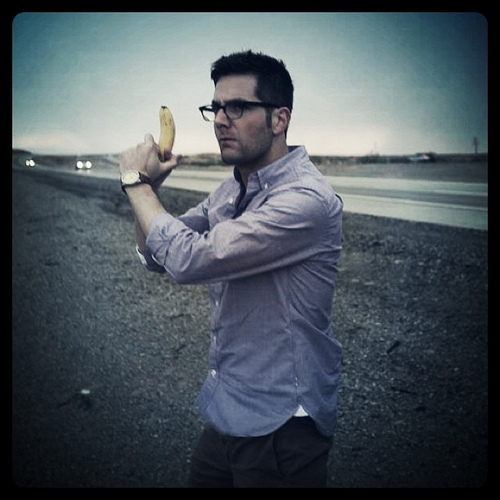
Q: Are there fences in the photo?
A: No, there are no fences.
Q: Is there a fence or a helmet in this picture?
A: No, there are no fences or helmets.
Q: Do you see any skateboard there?
A: No, there are no skateboards.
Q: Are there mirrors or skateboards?
A: No, there are no skateboards or mirrors.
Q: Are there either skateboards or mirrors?
A: No, there are no skateboards or mirrors.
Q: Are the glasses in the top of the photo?
A: Yes, the glasses are in the top of the image.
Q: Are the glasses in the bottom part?
A: No, the glasses are in the top of the image.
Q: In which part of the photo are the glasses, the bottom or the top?
A: The glasses are in the top of the image.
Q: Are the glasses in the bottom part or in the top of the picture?
A: The glasses are in the top of the image.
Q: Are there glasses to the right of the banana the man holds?
A: Yes, there are glasses to the right of the banana.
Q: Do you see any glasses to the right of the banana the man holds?
A: Yes, there are glasses to the right of the banana.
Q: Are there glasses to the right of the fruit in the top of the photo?
A: Yes, there are glasses to the right of the banana.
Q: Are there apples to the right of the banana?
A: No, there are glasses to the right of the banana.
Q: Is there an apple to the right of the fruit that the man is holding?
A: No, there are glasses to the right of the banana.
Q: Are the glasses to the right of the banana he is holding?
A: Yes, the glasses are to the right of the banana.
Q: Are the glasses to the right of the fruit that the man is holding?
A: Yes, the glasses are to the right of the banana.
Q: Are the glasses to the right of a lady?
A: No, the glasses are to the right of the banana.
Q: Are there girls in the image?
A: No, there are no girls.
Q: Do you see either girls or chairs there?
A: No, there are no girls or chairs.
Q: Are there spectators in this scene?
A: No, there are no spectators.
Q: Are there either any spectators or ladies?
A: No, there are no spectators or ladies.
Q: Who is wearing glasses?
A: The man is wearing glasses.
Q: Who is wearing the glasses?
A: The man is wearing glasses.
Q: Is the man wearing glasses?
A: Yes, the man is wearing glasses.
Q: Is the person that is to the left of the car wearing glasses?
A: Yes, the man is wearing glasses.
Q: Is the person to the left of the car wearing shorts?
A: No, the man is wearing glasses.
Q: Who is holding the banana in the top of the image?
A: The man is holding the banana.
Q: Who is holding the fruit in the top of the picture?
A: The man is holding the banana.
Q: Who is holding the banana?
A: The man is holding the banana.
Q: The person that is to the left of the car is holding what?
A: The man is holding the banana.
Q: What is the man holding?
A: The man is holding the banana.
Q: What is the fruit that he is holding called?
A: The fruit is a banana.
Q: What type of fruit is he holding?
A: The man is holding the banana.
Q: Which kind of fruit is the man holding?
A: The man is holding the banana.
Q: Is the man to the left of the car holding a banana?
A: Yes, the man is holding a banana.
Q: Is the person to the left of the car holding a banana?
A: Yes, the man is holding a banana.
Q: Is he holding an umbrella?
A: No, the man is holding a banana.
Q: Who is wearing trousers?
A: The man is wearing trousers.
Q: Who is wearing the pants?
A: The man is wearing trousers.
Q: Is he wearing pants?
A: Yes, the man is wearing pants.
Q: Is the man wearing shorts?
A: No, the man is wearing pants.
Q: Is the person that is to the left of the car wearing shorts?
A: No, the man is wearing pants.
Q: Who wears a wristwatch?
A: The man wears a wristwatch.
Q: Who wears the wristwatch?
A: The man wears a wristwatch.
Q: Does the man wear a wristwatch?
A: Yes, the man wears a wristwatch.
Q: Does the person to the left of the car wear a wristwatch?
A: Yes, the man wears a wristwatch.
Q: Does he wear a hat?
A: No, the man wears a wristwatch.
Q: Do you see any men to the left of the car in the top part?
A: Yes, there is a man to the left of the car.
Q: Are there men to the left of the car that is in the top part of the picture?
A: Yes, there is a man to the left of the car.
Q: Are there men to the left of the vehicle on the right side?
A: Yes, there is a man to the left of the car.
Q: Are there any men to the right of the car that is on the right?
A: No, the man is to the left of the car.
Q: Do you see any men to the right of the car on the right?
A: No, the man is to the left of the car.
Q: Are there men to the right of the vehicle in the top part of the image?
A: No, the man is to the left of the car.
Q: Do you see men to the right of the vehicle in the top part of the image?
A: No, the man is to the left of the car.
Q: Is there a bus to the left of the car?
A: No, there is a man to the left of the car.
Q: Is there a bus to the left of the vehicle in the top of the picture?
A: No, there is a man to the left of the car.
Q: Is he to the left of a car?
A: Yes, the man is to the left of a car.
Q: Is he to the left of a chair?
A: No, the man is to the left of a car.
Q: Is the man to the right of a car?
A: No, the man is to the left of a car.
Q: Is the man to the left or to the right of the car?
A: The man is to the left of the car.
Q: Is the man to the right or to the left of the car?
A: The man is to the left of the car.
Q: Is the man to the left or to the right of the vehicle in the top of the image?
A: The man is to the left of the car.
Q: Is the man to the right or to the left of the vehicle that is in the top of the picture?
A: The man is to the left of the car.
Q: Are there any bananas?
A: Yes, there is a banana.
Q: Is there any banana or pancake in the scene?
A: Yes, there is a banana.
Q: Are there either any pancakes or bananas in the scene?
A: Yes, there is a banana.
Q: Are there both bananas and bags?
A: No, there is a banana but no bags.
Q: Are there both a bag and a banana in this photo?
A: No, there is a banana but no bags.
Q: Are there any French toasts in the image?
A: No, there are no French toasts.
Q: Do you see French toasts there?
A: No, there are no French toasts.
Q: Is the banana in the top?
A: Yes, the banana is in the top of the image.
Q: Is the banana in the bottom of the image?
A: No, the banana is in the top of the image.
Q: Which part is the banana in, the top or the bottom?
A: The banana is in the top of the image.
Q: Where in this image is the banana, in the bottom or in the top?
A: The banana is in the top of the image.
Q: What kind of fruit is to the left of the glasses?
A: The fruit is a banana.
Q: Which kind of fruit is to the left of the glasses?
A: The fruit is a banana.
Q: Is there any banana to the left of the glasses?
A: Yes, there is a banana to the left of the glasses.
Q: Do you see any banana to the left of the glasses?
A: Yes, there is a banana to the left of the glasses.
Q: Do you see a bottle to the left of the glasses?
A: No, there is a banana to the left of the glasses.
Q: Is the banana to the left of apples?
A: No, the banana is to the left of the glasses.